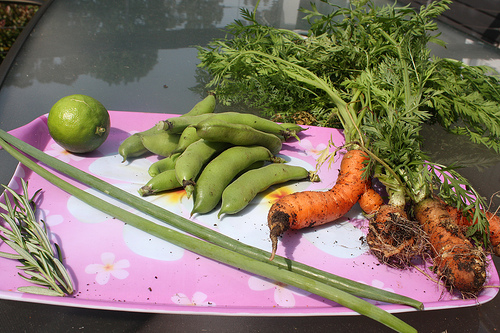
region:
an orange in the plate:
[41, 84, 122, 152]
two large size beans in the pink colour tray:
[3, 129, 441, 331]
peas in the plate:
[139, 82, 244, 224]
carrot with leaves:
[286, 11, 471, 246]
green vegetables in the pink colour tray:
[22, 113, 467, 302]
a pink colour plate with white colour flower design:
[45, 143, 434, 295]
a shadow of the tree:
[36, 0, 307, 95]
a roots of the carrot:
[364, 210, 429, 270]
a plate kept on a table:
[1, 70, 497, 311]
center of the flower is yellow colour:
[103, 263, 115, 272]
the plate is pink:
[82, 178, 237, 330]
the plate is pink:
[29, 120, 300, 331]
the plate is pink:
[130, 117, 261, 282]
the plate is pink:
[107, 165, 202, 290]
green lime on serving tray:
[45, 95, 110, 145]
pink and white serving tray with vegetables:
[0, 101, 499, 316]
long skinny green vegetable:
[0, 130, 420, 330]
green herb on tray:
[0, 180, 80, 295]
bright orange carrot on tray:
[265, 140, 370, 256]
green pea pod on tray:
[212, 160, 302, 211]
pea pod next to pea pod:
[185, 141, 270, 211]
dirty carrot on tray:
[416, 195, 481, 295]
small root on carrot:
[265, 215, 285, 260]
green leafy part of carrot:
[195, 7, 496, 200]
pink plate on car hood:
[39, 86, 458, 331]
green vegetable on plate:
[47, 84, 113, 149]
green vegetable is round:
[42, 86, 97, 148]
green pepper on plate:
[195, 141, 306, 218]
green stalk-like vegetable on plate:
[20, 129, 369, 324]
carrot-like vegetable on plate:
[290, 134, 365, 246]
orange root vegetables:
[373, 133, 469, 323]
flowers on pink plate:
[52, 224, 160, 309]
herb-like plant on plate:
[205, 32, 427, 159]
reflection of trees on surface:
[27, 2, 192, 99]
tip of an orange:
[98, 121, 125, 138]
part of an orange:
[77, 118, 89, 164]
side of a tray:
[157, 302, 174, 306]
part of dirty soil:
[266, 202, 274, 211]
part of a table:
[189, 307, 199, 320]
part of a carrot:
[295, 197, 325, 217]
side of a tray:
[201, 292, 228, 330]